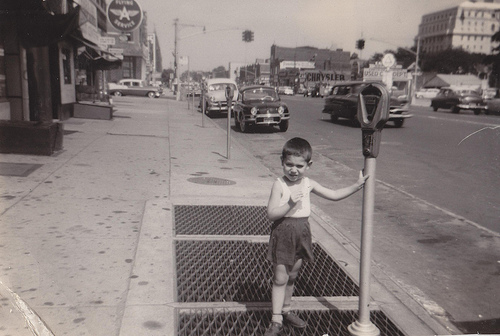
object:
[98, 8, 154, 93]
building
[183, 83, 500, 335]
paved street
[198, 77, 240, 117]
car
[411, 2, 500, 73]
building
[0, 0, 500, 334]
picture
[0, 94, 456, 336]
sidewalk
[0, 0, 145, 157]
building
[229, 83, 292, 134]
car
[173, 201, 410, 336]
sidewalk grate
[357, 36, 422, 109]
traffic lights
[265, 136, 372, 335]
child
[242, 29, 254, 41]
traffic signal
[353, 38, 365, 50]
traffic signal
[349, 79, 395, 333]
parking meter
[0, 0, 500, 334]
ago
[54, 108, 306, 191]
area